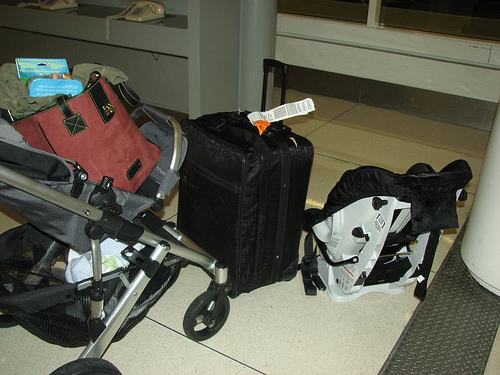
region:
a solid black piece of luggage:
[170, 107, 308, 292]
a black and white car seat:
[293, 154, 471, 310]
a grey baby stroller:
[0, 66, 222, 373]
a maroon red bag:
[16, 80, 162, 201]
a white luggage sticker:
[243, 100, 318, 125]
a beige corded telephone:
[102, 0, 165, 33]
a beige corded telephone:
[20, 0, 77, 17]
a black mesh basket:
[3, 226, 175, 345]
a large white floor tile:
[305, 99, 491, 191]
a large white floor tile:
[119, 182, 431, 373]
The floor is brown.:
[364, 113, 446, 166]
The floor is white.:
[273, 321, 366, 368]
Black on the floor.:
[407, 304, 490, 364]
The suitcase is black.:
[212, 180, 276, 239]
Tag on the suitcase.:
[249, 96, 316, 138]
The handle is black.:
[258, 59, 289, 112]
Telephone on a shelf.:
[90, 0, 173, 36]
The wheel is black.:
[173, 285, 237, 335]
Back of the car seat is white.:
[333, 211, 377, 247]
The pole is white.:
[459, 207, 498, 277]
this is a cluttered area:
[7, 42, 485, 369]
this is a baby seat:
[288, 92, 491, 327]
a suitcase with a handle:
[172, 45, 330, 320]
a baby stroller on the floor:
[0, 101, 262, 371]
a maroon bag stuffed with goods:
[3, 51, 167, 206]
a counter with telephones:
[9, 0, 478, 117]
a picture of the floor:
[22, 210, 421, 373]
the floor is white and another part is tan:
[276, 90, 498, 372]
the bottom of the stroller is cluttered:
[8, 223, 236, 364]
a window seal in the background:
[173, 0, 498, 76]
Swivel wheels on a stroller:
[182, 281, 229, 344]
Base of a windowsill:
[365, 0, 495, 60]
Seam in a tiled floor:
[207, 349, 244, 367]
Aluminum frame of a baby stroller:
[112, 238, 174, 322]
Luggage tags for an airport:
[242, 91, 319, 139]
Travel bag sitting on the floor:
[177, 101, 304, 293]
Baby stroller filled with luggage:
[0, 37, 202, 268]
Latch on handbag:
[96, 99, 122, 124]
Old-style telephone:
[122, 0, 168, 22]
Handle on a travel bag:
[252, 52, 297, 124]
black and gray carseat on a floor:
[301, 154, 473, 302]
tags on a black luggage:
[245, 95, 320, 135]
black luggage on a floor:
[176, 99, 321, 301]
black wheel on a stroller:
[177, 287, 238, 342]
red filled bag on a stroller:
[5, 57, 163, 192]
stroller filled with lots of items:
[0, 33, 231, 371]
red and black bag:
[9, 79, 164, 196]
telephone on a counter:
[94, 0, 171, 42]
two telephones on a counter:
[33, 1, 197, 40]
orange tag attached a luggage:
[254, 119, 270, 134]